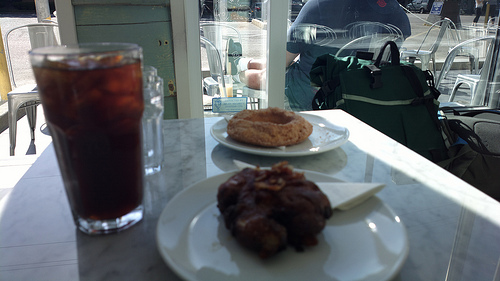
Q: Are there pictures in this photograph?
A: No, there are no pictures.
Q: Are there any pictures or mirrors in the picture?
A: No, there are no pictures or mirrors.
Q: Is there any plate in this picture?
A: Yes, there is a plate.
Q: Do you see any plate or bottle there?
A: Yes, there is a plate.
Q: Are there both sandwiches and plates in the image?
A: No, there is a plate but no sandwiches.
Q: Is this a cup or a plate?
A: This is a plate.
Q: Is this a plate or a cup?
A: This is a plate.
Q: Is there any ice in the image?
A: Yes, there is ice.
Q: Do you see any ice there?
A: Yes, there is ice.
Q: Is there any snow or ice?
A: Yes, there is ice.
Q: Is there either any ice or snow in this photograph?
A: Yes, there is ice.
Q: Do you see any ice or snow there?
A: Yes, there is ice.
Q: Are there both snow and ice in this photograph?
A: No, there is ice but no snow.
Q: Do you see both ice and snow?
A: No, there is ice but no snow.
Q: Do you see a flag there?
A: No, there are no flags.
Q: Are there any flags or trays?
A: No, there are no flags or trays.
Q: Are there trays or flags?
A: No, there are no flags or trays.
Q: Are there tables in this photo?
A: Yes, there is a table.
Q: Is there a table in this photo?
A: Yes, there is a table.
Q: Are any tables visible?
A: Yes, there is a table.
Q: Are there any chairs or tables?
A: Yes, there is a table.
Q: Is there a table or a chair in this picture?
A: Yes, there is a table.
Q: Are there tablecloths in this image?
A: No, there are no tablecloths.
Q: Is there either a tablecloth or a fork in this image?
A: No, there are no tablecloths or forks.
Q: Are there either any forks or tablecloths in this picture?
A: No, there are no tablecloths or forks.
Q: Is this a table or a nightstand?
A: This is a table.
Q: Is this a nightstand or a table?
A: This is a table.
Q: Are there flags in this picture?
A: No, there are no flags.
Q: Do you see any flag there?
A: No, there are no flags.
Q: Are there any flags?
A: No, there are no flags.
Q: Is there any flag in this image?
A: No, there are no flags.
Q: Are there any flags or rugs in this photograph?
A: No, there are no flags or rugs.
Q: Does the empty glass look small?
A: Yes, the glass is small.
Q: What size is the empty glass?
A: The glass is small.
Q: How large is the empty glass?
A: The glass is small.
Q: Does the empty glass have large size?
A: No, the glass is small.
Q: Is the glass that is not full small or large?
A: The glass is small.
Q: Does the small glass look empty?
A: Yes, the glass is empty.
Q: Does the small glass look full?
A: No, the glass is empty.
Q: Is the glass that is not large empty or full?
A: The glass is empty.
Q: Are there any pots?
A: No, there are no pots.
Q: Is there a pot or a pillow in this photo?
A: No, there are no pots or pillows.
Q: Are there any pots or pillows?
A: No, there are no pots or pillows.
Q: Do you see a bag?
A: Yes, there is a bag.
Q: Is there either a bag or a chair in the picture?
A: Yes, there is a bag.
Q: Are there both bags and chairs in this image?
A: Yes, there are both a bag and a chair.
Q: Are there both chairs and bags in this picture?
A: Yes, there are both a bag and a chair.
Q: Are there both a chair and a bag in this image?
A: Yes, there are both a bag and a chair.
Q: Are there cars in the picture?
A: No, there are no cars.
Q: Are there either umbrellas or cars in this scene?
A: No, there are no cars or umbrellas.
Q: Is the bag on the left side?
A: No, the bag is on the right of the image.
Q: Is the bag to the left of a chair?
A: Yes, the bag is to the left of a chair.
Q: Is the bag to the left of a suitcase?
A: No, the bag is to the left of a chair.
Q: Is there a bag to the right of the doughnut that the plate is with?
A: Yes, there is a bag to the right of the doughnut.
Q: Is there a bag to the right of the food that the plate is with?
A: Yes, there is a bag to the right of the doughnut.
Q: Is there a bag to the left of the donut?
A: No, the bag is to the right of the donut.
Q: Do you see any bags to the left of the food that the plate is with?
A: No, the bag is to the right of the donut.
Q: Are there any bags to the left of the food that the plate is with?
A: No, the bag is to the right of the donut.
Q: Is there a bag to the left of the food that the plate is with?
A: No, the bag is to the right of the donut.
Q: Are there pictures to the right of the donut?
A: No, there is a bag to the right of the donut.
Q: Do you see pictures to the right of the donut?
A: No, there is a bag to the right of the donut.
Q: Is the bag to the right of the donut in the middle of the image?
A: Yes, the bag is to the right of the donut.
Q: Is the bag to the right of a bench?
A: No, the bag is to the right of the donut.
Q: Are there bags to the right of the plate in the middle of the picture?
A: Yes, there is a bag to the right of the plate.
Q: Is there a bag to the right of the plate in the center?
A: Yes, there is a bag to the right of the plate.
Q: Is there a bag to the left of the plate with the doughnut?
A: No, the bag is to the right of the plate.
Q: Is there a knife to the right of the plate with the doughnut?
A: No, there is a bag to the right of the plate.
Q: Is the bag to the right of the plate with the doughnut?
A: Yes, the bag is to the right of the plate.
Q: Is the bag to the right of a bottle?
A: No, the bag is to the right of the plate.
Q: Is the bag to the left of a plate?
A: No, the bag is to the right of a plate.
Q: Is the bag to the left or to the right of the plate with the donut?
A: The bag is to the right of the plate.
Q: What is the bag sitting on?
A: The bag is sitting on the chair.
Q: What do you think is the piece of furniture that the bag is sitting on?
A: The piece of furniture is a chair.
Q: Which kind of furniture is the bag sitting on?
A: The bag is sitting on the chair.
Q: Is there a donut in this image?
A: Yes, there is a donut.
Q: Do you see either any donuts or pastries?
A: Yes, there is a donut.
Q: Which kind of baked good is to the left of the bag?
A: The food is a donut.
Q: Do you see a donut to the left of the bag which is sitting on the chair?
A: Yes, there is a donut to the left of the bag.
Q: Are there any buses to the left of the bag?
A: No, there is a donut to the left of the bag.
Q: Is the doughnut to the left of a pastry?
A: No, the doughnut is to the left of the bag.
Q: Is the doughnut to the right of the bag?
A: No, the doughnut is to the left of the bag.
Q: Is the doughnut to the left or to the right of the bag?
A: The doughnut is to the left of the bag.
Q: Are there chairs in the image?
A: Yes, there is a chair.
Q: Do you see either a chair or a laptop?
A: Yes, there is a chair.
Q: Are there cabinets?
A: No, there are no cabinets.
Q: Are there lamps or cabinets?
A: No, there are no cabinets or lamps.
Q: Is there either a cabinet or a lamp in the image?
A: No, there are no cabinets or lamps.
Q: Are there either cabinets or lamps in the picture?
A: No, there are no cabinets or lamps.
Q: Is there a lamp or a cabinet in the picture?
A: No, there are no cabinets or lamps.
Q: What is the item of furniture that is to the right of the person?
A: The piece of furniture is a chair.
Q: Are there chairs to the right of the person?
A: Yes, there is a chair to the right of the person.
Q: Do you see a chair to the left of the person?
A: No, the chair is to the right of the person.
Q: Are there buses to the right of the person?
A: No, there is a chair to the right of the person.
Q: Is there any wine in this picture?
A: No, there is no wine.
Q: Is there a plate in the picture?
A: Yes, there is a plate.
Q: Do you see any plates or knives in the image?
A: Yes, there is a plate.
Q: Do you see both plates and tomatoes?
A: No, there is a plate but no tomatoes.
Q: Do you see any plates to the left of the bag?
A: Yes, there is a plate to the left of the bag.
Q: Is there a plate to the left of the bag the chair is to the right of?
A: Yes, there is a plate to the left of the bag.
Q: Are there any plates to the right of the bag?
A: No, the plate is to the left of the bag.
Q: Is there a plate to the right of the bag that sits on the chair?
A: No, the plate is to the left of the bag.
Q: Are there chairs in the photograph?
A: Yes, there is a chair.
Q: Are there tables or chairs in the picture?
A: Yes, there is a chair.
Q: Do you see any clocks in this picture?
A: No, there are no clocks.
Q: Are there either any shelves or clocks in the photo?
A: No, there are no clocks or shelves.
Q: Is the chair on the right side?
A: Yes, the chair is on the right of the image.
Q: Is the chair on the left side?
A: No, the chair is on the right of the image.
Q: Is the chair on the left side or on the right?
A: The chair is on the right of the image.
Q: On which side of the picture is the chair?
A: The chair is on the right of the image.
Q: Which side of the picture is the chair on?
A: The chair is on the right of the image.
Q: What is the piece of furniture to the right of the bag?
A: The piece of furniture is a chair.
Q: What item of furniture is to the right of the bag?
A: The piece of furniture is a chair.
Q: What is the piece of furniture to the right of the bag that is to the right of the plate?
A: The piece of furniture is a chair.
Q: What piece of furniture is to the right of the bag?
A: The piece of furniture is a chair.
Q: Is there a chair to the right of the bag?
A: Yes, there is a chair to the right of the bag.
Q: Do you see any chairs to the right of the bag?
A: Yes, there is a chair to the right of the bag.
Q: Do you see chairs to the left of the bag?
A: No, the chair is to the right of the bag.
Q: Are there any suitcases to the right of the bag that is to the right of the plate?
A: No, there is a chair to the right of the bag.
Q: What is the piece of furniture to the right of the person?
A: The piece of furniture is a chair.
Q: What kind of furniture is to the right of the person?
A: The piece of furniture is a chair.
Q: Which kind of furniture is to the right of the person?
A: The piece of furniture is a chair.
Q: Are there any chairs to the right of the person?
A: Yes, there is a chair to the right of the person.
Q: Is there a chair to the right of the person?
A: Yes, there is a chair to the right of the person.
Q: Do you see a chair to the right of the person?
A: Yes, there is a chair to the right of the person.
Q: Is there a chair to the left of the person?
A: No, the chair is to the right of the person.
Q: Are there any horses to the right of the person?
A: No, there is a chair to the right of the person.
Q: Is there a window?
A: Yes, there is a window.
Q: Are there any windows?
A: Yes, there is a window.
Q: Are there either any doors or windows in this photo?
A: Yes, there is a window.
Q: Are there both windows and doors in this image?
A: No, there is a window but no doors.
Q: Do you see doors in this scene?
A: No, there are no doors.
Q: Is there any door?
A: No, there are no doors.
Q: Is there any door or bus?
A: No, there are no doors or buses.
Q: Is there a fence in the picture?
A: No, there are no fences.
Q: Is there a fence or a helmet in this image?
A: No, there are no fences or helmets.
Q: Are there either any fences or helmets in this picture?
A: No, there are no fences or helmets.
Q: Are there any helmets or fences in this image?
A: No, there are no fences or helmets.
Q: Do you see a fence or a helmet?
A: No, there are no fences or helmets.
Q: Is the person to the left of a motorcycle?
A: No, the person is to the left of the chair.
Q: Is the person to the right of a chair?
A: No, the person is to the left of a chair.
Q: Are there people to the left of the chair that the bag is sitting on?
A: Yes, there is a person to the left of the chair.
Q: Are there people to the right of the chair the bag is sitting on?
A: No, the person is to the left of the chair.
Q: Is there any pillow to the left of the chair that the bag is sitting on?
A: No, there is a person to the left of the chair.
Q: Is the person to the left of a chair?
A: Yes, the person is to the left of a chair.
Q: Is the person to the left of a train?
A: No, the person is to the left of a chair.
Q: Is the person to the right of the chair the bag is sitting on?
A: No, the person is to the left of the chair.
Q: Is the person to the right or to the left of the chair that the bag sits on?
A: The person is to the left of the chair.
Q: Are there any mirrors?
A: No, there are no mirrors.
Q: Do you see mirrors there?
A: No, there are no mirrors.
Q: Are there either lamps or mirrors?
A: No, there are no mirrors or lamps.